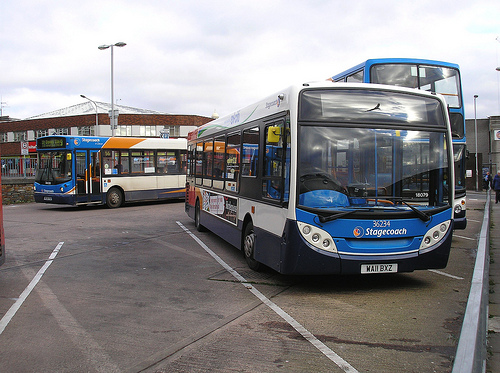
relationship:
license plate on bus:
[360, 259, 400, 277] [183, 78, 455, 279]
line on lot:
[182, 221, 364, 366] [3, 173, 483, 363]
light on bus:
[302, 224, 334, 247] [183, 78, 455, 279]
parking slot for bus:
[0, 220, 360, 370] [183, 78, 455, 279]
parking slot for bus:
[0, 220, 360, 370] [30, 137, 185, 205]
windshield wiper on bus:
[316, 205, 374, 224] [183, 78, 455, 279]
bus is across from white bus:
[183, 78, 455, 279] [30, 137, 185, 205]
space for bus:
[5, 211, 340, 371] [183, 78, 458, 283]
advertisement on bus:
[186, 181, 242, 228] [183, 78, 458, 283]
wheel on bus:
[240, 219, 266, 271] [183, 78, 455, 279]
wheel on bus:
[211, 181, 281, 279] [135, 48, 470, 300]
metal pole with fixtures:
[100, 51, 127, 135] [95, 39, 134, 55]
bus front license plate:
[183, 78, 458, 283] [356, 261, 402, 278]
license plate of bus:
[360, 259, 400, 277] [183, 78, 455, 279]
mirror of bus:
[255, 112, 287, 148] [197, 95, 454, 287]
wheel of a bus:
[106, 185, 128, 209] [29, 130, 186, 209]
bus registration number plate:
[183, 78, 455, 279] [361, 263, 398, 274]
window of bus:
[299, 125, 450, 207] [183, 78, 455, 279]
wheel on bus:
[106, 182, 127, 212] [20, 122, 198, 214]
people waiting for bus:
[475, 162, 498, 199] [165, 71, 470, 279]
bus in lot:
[183, 78, 458, 283] [16, 188, 493, 370]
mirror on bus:
[260, 123, 282, 151] [183, 78, 455, 279]